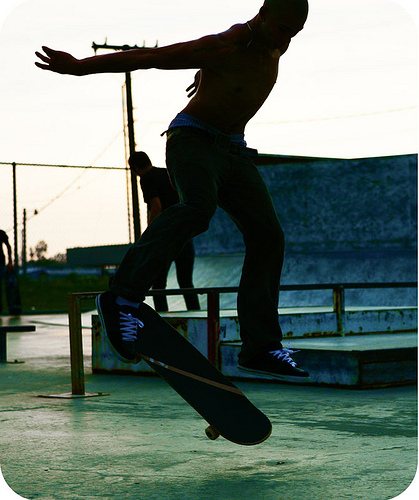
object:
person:
[34, 0, 319, 383]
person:
[125, 150, 202, 315]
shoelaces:
[116, 306, 145, 347]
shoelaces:
[265, 343, 302, 370]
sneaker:
[92, 288, 150, 365]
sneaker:
[236, 343, 311, 383]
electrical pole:
[91, 34, 158, 250]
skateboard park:
[0, 147, 416, 499]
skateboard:
[111, 293, 275, 446]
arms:
[78, 26, 247, 78]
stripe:
[141, 358, 246, 395]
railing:
[69, 279, 419, 401]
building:
[63, 241, 139, 269]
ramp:
[87, 245, 416, 311]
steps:
[218, 328, 417, 389]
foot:
[234, 332, 312, 384]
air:
[0, 0, 418, 175]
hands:
[33, 45, 80, 81]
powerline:
[247, 104, 418, 126]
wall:
[175, 153, 418, 252]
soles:
[92, 294, 127, 364]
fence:
[0, 157, 159, 271]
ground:
[0, 298, 416, 499]